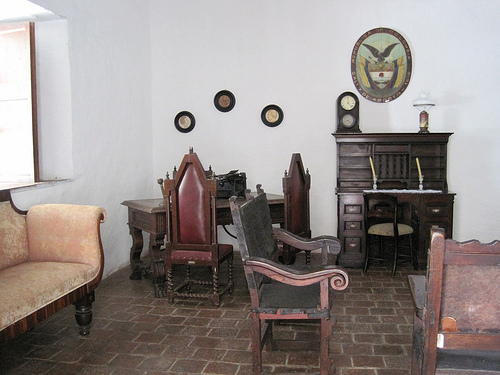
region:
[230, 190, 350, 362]
chair in middle of room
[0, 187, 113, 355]
couch by the window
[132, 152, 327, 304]
desk with chairs around it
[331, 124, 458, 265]
desk with items on it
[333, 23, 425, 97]
image on the wall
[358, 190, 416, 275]
chair at desk area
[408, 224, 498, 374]
chair facing desk and chair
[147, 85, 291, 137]
images on wall above desk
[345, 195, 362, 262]
drawers on the desk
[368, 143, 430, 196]
pen in ink containers on desk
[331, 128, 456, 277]
Desk against the wall.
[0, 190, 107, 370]
Beige sofa by the window.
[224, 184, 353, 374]
Chair in the middle of the room.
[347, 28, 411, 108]
Picture on the wall.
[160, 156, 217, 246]
Maroon cushion on chair back.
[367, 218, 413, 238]
Brown cushion on chair seat.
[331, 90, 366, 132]
Clock on the desk.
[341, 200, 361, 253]
Drawers in the desk.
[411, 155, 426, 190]
Candle on the desk.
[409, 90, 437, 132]
Lamp on the desk.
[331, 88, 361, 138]
wooden mantel clock sitting on desk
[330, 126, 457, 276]
old dark wooden desk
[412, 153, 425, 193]
candlestick sitting on desk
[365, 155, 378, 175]
candle resting in candlestick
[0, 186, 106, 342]
antinque wood and upholstered sofa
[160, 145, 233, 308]
old wooden chair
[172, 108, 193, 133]
small framed picture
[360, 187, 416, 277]
small wooden chair in front of desk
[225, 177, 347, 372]
old wooden sette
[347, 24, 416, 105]
picture hangning on wall above desk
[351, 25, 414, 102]
The frame over the desk.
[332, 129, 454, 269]
The desk below the frame.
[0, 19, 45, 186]
The window in the room.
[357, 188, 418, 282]
The chair in front of the desk.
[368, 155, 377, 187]
The candle on the desk on the left.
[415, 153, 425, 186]
The candle on the desk on the right.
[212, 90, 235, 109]
The circle frame in the middle.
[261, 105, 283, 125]
The circle frame on the right.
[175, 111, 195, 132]
The circle frame on the left.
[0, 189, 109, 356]
The tan sofa against the windowsill.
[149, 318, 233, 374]
brick flooring on ground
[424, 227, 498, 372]
wooden chair in room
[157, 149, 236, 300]
older style chair in room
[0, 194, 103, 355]
small peach colored couch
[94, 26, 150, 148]
white painted wall in room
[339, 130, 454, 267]
brown wooden desk in room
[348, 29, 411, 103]
picture of eagle on wall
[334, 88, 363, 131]
small clock on desk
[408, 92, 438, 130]
lamp on the desk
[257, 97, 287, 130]
black record on wall